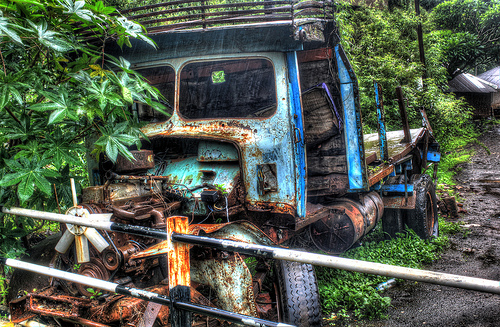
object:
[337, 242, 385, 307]
weeds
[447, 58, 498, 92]
roofs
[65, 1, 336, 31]
fence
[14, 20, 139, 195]
tree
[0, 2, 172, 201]
bushes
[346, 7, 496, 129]
bushes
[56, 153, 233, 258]
engine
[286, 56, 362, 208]
door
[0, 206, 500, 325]
bar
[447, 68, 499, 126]
building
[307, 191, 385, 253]
barrel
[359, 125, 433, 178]
truck bed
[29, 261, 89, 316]
floor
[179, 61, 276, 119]
window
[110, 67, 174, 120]
window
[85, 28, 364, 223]
truck cab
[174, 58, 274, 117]
windshield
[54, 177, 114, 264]
fan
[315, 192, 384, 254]
gas tank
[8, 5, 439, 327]
rusty truck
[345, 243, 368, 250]
exhaust pipe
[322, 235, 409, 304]
grass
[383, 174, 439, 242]
wheel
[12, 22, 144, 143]
leaves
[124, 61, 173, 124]
windshield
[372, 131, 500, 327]
path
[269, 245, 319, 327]
tire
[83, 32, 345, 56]
railing